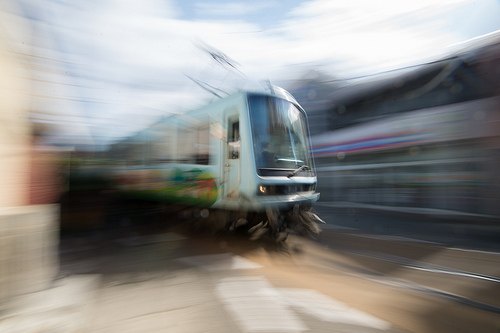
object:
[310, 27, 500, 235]
bullet train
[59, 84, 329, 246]
train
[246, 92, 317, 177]
windshield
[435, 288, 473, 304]
tracks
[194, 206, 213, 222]
wheels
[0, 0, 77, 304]
train depot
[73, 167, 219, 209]
logo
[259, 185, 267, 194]
headlight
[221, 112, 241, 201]
door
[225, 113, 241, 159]
window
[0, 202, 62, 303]
wall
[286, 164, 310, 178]
wiper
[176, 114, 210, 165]
window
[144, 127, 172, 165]
window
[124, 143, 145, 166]
window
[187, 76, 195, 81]
wires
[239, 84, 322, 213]
front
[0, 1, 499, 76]
sky